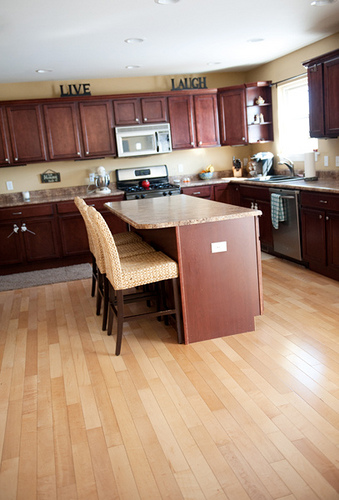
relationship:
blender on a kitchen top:
[91, 166, 111, 194] [1, 184, 125, 207]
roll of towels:
[302, 151, 315, 176] [298, 146, 317, 178]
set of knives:
[231, 157, 240, 169] [221, 147, 256, 177]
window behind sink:
[264, 76, 323, 161] [252, 161, 301, 184]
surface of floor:
[3, 256, 335, 498] [154, 24, 244, 52]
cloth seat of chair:
[260, 194, 290, 232] [89, 205, 181, 357]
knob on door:
[198, 140, 203, 145] [43, 102, 81, 160]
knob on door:
[324, 214, 329, 220] [111, 95, 142, 126]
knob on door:
[318, 213, 322, 218] [193, 91, 220, 148]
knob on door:
[134, 117, 139, 120] [301, 198, 326, 272]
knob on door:
[77, 152, 80, 155] [324, 203, 336, 279]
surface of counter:
[104, 195, 262, 231] [101, 193, 261, 231]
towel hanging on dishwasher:
[268, 193, 284, 224] [265, 181, 305, 265]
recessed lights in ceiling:
[115, 24, 147, 73] [1, 0, 317, 67]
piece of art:
[58, 84, 91, 96] [60, 75, 95, 103]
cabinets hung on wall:
[34, 107, 231, 179] [1, 66, 335, 194]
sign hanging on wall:
[39, 167, 60, 182] [0, 74, 251, 274]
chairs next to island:
[73, 195, 183, 357] [100, 189, 267, 345]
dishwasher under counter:
[266, 186, 302, 264] [234, 173, 338, 193]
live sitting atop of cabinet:
[56, 81, 93, 95] [0, 80, 265, 165]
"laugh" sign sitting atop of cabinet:
[165, 74, 209, 91] [0, 88, 263, 164]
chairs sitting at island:
[85, 206, 177, 348] [107, 195, 266, 348]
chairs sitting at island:
[73, 195, 183, 357] [107, 195, 266, 348]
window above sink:
[276, 75, 320, 158] [250, 170, 313, 192]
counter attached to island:
[101, 194, 262, 231] [100, 189, 267, 345]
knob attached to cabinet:
[199, 141, 202, 146] [184, 136, 214, 155]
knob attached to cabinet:
[326, 216, 329, 220] [297, 205, 331, 280]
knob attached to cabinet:
[84, 149, 93, 157] [76, 90, 120, 162]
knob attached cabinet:
[11, 156, 19, 162] [2, 95, 53, 173]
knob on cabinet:
[191, 140, 194, 144] [168, 96, 194, 149]